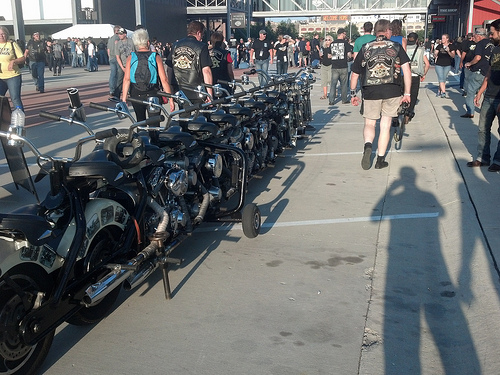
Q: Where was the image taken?
A: It was taken at the sidewalk.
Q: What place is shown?
A: It is a sidewalk.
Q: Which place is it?
A: It is a sidewalk.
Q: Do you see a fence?
A: No, there are no fences.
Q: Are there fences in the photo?
A: No, there are no fences.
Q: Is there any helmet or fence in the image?
A: No, there are no fences or helmets.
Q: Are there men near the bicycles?
A: Yes, there is a man near the bicycles.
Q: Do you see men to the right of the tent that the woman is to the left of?
A: Yes, there is a man to the right of the tent.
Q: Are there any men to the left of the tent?
A: No, the man is to the right of the tent.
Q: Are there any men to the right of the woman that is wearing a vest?
A: Yes, there is a man to the right of the woman.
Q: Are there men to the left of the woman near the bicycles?
A: No, the man is to the right of the woman.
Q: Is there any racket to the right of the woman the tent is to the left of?
A: No, there is a man to the right of the woman.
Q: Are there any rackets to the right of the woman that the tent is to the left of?
A: No, there is a man to the right of the woman.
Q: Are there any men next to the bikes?
A: Yes, there is a man next to the bikes.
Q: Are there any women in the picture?
A: Yes, there is a woman.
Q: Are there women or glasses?
A: Yes, there is a woman.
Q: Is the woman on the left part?
A: Yes, the woman is on the left of the image.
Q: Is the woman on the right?
A: No, the woman is on the left of the image.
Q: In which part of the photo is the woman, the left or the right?
A: The woman is on the left of the image.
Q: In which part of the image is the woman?
A: The woman is on the left of the image.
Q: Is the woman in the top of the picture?
A: Yes, the woman is in the top of the image.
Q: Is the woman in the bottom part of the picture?
A: No, the woman is in the top of the image.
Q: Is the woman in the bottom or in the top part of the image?
A: The woman is in the top of the image.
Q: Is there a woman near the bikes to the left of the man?
A: Yes, there is a woman near the bikes.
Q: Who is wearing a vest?
A: The woman is wearing a vest.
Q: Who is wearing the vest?
A: The woman is wearing a vest.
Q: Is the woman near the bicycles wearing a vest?
A: Yes, the woman is wearing a vest.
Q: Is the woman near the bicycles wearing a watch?
A: No, the woman is wearing a vest.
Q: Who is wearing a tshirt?
A: The woman is wearing a tshirt.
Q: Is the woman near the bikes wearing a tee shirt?
A: Yes, the woman is wearing a tee shirt.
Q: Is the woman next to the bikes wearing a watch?
A: No, the woman is wearing a tee shirt.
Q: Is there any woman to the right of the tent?
A: Yes, there is a woman to the right of the tent.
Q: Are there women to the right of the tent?
A: Yes, there is a woman to the right of the tent.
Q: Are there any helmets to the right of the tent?
A: No, there is a woman to the right of the tent.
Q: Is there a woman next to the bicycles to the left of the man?
A: Yes, there is a woman next to the bicycles.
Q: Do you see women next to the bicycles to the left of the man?
A: Yes, there is a woman next to the bicycles.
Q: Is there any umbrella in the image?
A: No, there are no umbrellas.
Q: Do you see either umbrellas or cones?
A: No, there are no umbrellas or cones.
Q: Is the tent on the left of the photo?
A: Yes, the tent is on the left of the image.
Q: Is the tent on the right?
A: No, the tent is on the left of the image.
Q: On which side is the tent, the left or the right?
A: The tent is on the left of the image.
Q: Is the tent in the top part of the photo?
A: Yes, the tent is in the top of the image.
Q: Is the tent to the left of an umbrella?
A: No, the tent is to the left of a man.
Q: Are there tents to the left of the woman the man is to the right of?
A: Yes, there is a tent to the left of the woman.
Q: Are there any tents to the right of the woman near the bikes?
A: No, the tent is to the left of the woman.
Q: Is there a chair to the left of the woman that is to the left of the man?
A: No, there is a tent to the left of the woman.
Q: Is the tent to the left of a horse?
A: No, the tent is to the left of a woman.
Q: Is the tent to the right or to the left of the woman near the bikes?
A: The tent is to the left of the woman.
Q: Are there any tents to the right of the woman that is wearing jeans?
A: Yes, there is a tent to the right of the woman.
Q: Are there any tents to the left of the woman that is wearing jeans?
A: No, the tent is to the right of the woman.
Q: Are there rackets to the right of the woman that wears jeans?
A: No, there is a tent to the right of the woman.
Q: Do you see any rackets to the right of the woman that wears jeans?
A: No, there is a tent to the right of the woman.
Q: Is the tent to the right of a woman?
A: Yes, the tent is to the right of a woman.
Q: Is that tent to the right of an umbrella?
A: No, the tent is to the right of a woman.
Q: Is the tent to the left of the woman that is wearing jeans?
A: No, the tent is to the right of the woman.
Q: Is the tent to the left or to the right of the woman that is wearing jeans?
A: The tent is to the right of the woman.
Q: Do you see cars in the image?
A: No, there are no cars.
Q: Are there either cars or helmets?
A: No, there are no cars or helmets.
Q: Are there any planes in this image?
A: No, there are no planes.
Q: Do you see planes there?
A: No, there are no planes.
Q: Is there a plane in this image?
A: No, there are no airplanes.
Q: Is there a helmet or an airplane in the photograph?
A: No, there are no airplanes or helmets.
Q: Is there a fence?
A: No, there are no fences.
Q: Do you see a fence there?
A: No, there are no fences.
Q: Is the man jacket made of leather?
A: Yes, the jacket is made of leather.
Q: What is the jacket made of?
A: The jacket is made of leather.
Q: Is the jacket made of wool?
A: No, the jacket is made of leather.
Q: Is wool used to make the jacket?
A: No, the jacket is made of leather.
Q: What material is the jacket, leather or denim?
A: The jacket is made of leather.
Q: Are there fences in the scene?
A: No, there are no fences.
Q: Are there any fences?
A: No, there are no fences.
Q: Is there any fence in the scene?
A: No, there are no fences.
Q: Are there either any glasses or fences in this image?
A: No, there are no fences or glasses.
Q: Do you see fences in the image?
A: No, there are no fences.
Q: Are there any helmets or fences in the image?
A: No, there are no fences or helmets.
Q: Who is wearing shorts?
A: The man is wearing shorts.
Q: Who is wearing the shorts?
A: The man is wearing shorts.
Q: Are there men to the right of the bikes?
A: Yes, there is a man to the right of the bikes.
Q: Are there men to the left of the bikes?
A: No, the man is to the right of the bikes.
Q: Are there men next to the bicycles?
A: Yes, there is a man next to the bicycles.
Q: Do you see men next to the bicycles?
A: Yes, there is a man next to the bicycles.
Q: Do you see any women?
A: Yes, there is a woman.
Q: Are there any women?
A: Yes, there is a woman.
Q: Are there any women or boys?
A: Yes, there is a woman.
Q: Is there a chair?
A: No, there are no chairs.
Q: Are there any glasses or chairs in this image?
A: No, there are no chairs or glasses.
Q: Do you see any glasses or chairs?
A: No, there are no chairs or glasses.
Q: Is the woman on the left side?
A: Yes, the woman is on the left of the image.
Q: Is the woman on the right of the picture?
A: No, the woman is on the left of the image.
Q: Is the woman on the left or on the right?
A: The woman is on the left of the image.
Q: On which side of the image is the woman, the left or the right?
A: The woman is on the left of the image.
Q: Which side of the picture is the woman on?
A: The woman is on the left of the image.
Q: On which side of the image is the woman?
A: The woman is on the left of the image.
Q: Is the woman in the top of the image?
A: Yes, the woman is in the top of the image.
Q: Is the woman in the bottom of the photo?
A: No, the woman is in the top of the image.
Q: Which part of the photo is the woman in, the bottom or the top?
A: The woman is in the top of the image.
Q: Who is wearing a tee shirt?
A: The woman is wearing a tee shirt.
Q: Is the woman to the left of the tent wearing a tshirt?
A: Yes, the woman is wearing a tshirt.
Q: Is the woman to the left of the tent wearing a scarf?
A: No, the woman is wearing a tshirt.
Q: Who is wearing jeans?
A: The woman is wearing jeans.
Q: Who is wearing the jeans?
A: The woman is wearing jeans.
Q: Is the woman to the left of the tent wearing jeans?
A: Yes, the woman is wearing jeans.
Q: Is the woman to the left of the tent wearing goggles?
A: No, the woman is wearing jeans.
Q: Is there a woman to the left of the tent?
A: Yes, there is a woman to the left of the tent.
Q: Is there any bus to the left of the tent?
A: No, there is a woman to the left of the tent.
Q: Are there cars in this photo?
A: No, there are no cars.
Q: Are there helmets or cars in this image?
A: No, there are no cars or helmets.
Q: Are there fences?
A: No, there are no fences.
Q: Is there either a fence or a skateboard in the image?
A: No, there are no fences or skateboards.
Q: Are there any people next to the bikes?
A: Yes, there is a person next to the bikes.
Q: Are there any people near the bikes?
A: Yes, there is a person near the bikes.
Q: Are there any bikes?
A: Yes, there are bikes.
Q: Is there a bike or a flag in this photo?
A: Yes, there are bikes.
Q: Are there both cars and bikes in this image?
A: No, there are bikes but no cars.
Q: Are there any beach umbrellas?
A: No, there are no beach umbrellas.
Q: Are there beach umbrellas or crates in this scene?
A: No, there are no beach umbrellas or crates.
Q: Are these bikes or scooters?
A: These are bikes.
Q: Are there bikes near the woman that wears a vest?
A: Yes, there are bikes near the woman.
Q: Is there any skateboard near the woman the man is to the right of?
A: No, there are bikes near the woman.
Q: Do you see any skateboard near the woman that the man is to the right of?
A: No, there are bikes near the woman.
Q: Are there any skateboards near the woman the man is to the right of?
A: No, there are bikes near the woman.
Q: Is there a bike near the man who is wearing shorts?
A: Yes, there are bikes near the man.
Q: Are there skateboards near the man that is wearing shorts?
A: No, there are bikes near the man.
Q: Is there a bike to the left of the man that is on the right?
A: Yes, there are bikes to the left of the man.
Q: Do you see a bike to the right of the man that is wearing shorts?
A: No, the bikes are to the left of the man.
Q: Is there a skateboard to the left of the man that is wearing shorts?
A: No, there are bikes to the left of the man.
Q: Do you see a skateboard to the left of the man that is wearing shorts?
A: No, there are bikes to the left of the man.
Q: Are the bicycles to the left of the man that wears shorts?
A: Yes, the bicycles are to the left of the man.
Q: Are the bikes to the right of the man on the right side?
A: No, the bikes are to the left of the man.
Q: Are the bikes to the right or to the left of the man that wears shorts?
A: The bikes are to the left of the man.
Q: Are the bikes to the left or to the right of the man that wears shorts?
A: The bikes are to the left of the man.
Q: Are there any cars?
A: No, there are no cars.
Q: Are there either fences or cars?
A: No, there are no cars or fences.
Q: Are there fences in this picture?
A: No, there are no fences.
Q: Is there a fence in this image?
A: No, there are no fences.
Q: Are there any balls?
A: No, there are no balls.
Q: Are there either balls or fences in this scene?
A: No, there are no balls or fences.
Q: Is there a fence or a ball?
A: No, there are no balls or fences.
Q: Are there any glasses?
A: No, there are no glasses.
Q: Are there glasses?
A: No, there are no glasses.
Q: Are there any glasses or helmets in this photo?
A: No, there are no glasses or helmets.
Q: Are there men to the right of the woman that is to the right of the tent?
A: Yes, there is a man to the right of the woman.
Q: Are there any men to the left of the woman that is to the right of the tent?
A: No, the man is to the right of the woman.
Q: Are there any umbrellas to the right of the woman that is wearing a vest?
A: No, there is a man to the right of the woman.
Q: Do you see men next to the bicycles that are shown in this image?
A: Yes, there is a man next to the bicycles.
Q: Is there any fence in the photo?
A: No, there are no fences.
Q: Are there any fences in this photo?
A: No, there are no fences.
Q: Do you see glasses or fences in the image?
A: No, there are no fences or glasses.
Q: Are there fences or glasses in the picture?
A: No, there are no fences or glasses.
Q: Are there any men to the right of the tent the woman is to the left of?
A: Yes, there is a man to the right of the tent.